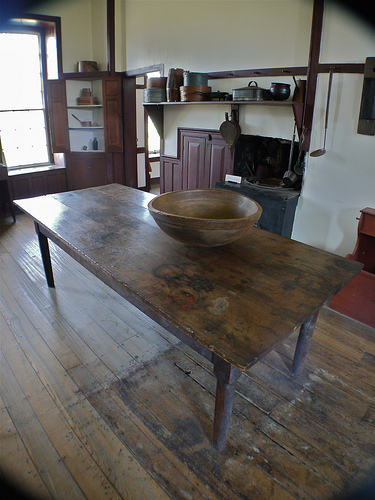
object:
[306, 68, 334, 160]
ladle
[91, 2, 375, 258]
wall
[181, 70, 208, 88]
pots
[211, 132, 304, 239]
stove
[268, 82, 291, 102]
black cauldron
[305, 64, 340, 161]
untensil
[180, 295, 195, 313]
paint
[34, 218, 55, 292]
wooden leg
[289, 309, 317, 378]
wooden leg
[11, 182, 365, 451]
table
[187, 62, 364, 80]
rack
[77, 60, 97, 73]
pot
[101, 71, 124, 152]
doors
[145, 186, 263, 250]
bowl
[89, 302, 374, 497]
damaged floor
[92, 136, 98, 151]
bottle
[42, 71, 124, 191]
cabinet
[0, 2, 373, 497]
kitchen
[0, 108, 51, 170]
window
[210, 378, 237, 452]
leg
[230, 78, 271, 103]
container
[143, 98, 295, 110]
shelf